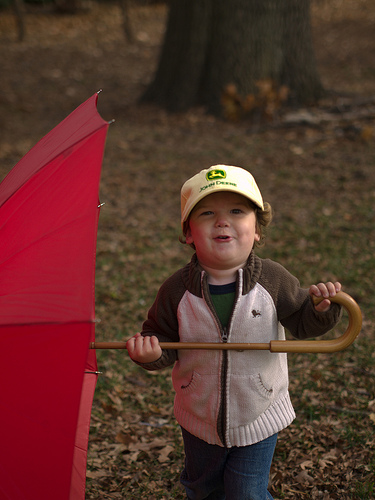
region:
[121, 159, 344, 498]
Little boy holding umbrella.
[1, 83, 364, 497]
Red umbrella in the boy's hands.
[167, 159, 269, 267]
Hat on the boy.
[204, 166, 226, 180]
yellow deer on the hat.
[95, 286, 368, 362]
Wooden handle on the umbrella.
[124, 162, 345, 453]
Brown sweater on the boy.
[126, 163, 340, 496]
Blue jeans on the boy.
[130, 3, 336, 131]
Tree trunk in the background.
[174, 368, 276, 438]
Pockets on the sweater.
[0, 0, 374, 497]
Brown leaves on the ground.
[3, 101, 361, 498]
it is an umbrella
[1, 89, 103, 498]
it is a red color umbrella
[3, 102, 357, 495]
boy holding a umbrella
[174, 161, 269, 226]
boy wearing cap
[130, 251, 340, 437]
boy wearing sweater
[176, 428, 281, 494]
boy wearing blue color pant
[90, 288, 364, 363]
brown color umbrella stick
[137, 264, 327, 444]
brown with white color sweater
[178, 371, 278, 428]
packets in the sweater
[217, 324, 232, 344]
it is a sweater zip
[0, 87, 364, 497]
young boy holding an umbrella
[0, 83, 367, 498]
young boy holding a red umbrella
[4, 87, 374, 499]
young boy holding an umbrella sideways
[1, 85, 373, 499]
young boy holding a large red umbrella sideways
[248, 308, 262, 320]
small design on a young boy's jacket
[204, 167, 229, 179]
John Deere logo on a hat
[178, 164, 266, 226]
John Deere hat on a young boy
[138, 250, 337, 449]
brown jacket on a young boy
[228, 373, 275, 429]
pocket on a young boy's jacket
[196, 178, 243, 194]
green text on a cap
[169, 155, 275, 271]
Hat on boy's head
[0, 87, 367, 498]
An open red umbrella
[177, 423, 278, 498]
A pair of blue jeans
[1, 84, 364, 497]
A boy is holding an umbrella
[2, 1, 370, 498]
Leaves are on the grass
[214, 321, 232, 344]
A zipper on a sweater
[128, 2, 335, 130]
A brown tree trunk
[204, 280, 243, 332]
A shirt is green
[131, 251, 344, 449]
A brown and off white sweater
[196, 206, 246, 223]
A pair of eyes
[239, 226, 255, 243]
the little boy has dipples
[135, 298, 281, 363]
he is holding the umbrella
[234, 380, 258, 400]
the sweater is white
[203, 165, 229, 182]
the emblem has a deer on it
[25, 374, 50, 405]
the umbrella is red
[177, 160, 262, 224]
he is wearing a hat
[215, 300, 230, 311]
the shirt is green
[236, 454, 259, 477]
the pants are blue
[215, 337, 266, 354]
the handle is brown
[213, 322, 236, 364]
the sweater is zipped up